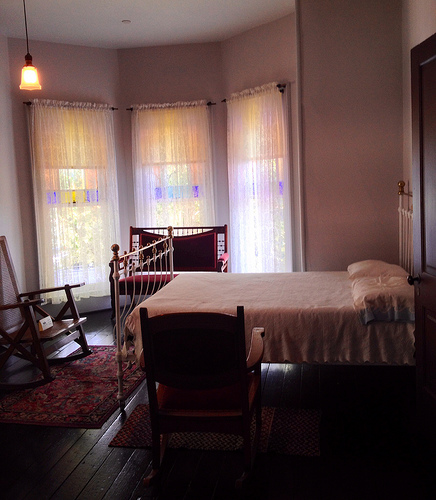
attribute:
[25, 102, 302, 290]
curtain — white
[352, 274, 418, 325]
pillow — blue, white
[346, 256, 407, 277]
pillow — white, blue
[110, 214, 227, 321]
sofa — small, wood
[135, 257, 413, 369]
sheet — white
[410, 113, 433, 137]
ground — red, upholstered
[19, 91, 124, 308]
windows — tall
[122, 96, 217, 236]
windows — tall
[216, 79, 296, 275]
windows — tall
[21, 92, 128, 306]
curtains — light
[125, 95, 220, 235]
curtains — light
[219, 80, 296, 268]
curtains — light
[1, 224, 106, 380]
chair — high back rocking chair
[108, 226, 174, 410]
frame — metal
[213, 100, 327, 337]
curtain — white, sheer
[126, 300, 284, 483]
chair — short, wooden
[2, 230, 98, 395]
chair — wooden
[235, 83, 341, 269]
wall curtain — beautiful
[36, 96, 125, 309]
curtain — beautiful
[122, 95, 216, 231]
curtain — beautiful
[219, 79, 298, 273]
curtain — beautiful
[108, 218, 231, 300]
chair — upholstered, red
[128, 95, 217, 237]
curtain — white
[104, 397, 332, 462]
carpet — brown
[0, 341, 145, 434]
carpet — brown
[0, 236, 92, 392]
rocking chair — wooden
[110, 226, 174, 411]
foot board — wire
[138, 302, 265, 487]
chair — wooden, rocking chair, red, upholstered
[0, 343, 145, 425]
rug — large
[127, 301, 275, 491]
chair — wood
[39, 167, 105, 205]
window — stained, glass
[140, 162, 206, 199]
window — stained, glass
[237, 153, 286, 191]
window — stained, glass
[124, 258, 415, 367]
bed — twin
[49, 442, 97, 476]
floor — wooden, dark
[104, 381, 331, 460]
rug — small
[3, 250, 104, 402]
rocking chair — wood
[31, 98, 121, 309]
curtain — white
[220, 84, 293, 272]
curtain — white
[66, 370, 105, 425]
rug — ornate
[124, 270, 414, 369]
sheets — white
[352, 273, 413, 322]
pillow — white, blue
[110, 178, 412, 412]
frame — metal, bed frame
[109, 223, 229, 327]
bench — indoor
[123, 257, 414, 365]
blanket — white